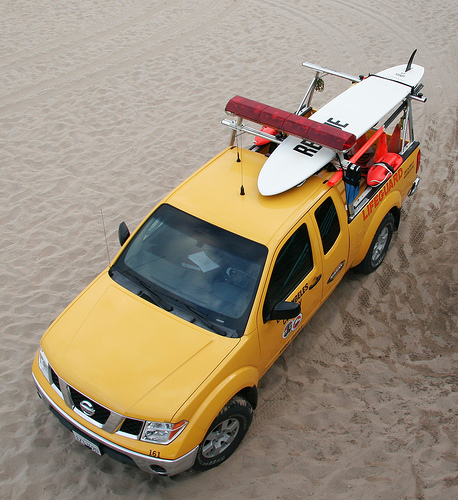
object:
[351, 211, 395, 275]
back tire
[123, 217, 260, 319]
wipers windshield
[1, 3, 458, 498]
sand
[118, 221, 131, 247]
mirror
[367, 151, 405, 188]
saving device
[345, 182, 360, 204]
fins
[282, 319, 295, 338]
emblem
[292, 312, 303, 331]
emblem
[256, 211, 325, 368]
truck door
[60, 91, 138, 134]
ground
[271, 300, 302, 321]
mirror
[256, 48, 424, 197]
surfboard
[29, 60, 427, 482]
car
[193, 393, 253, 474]
front wheel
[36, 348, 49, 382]
headlight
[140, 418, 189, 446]
headlight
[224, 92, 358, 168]
light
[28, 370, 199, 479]
bumper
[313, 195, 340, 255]
window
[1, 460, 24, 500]
footprints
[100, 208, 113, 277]
antennae